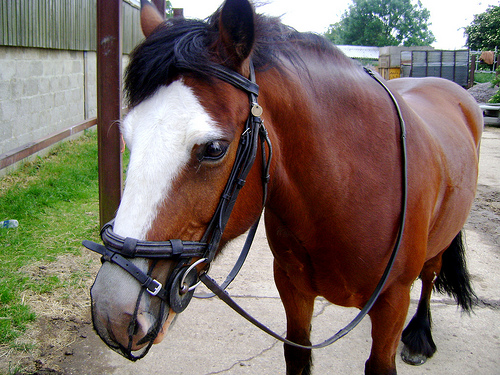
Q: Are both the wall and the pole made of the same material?
A: No, the wall is made of concrete and the pole is made of metal.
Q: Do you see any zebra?
A: No, there are no zebras.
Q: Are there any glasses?
A: No, there are no glasses.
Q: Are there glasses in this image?
A: No, there are no glasses.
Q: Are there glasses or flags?
A: No, there are no glasses or flags.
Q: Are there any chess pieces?
A: No, there are no chess pieces.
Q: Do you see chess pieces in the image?
A: No, there are no chess pieces.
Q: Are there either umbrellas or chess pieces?
A: No, there are no chess pieces or umbrellas.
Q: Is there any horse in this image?
A: Yes, there is a horse.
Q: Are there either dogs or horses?
A: Yes, there is a horse.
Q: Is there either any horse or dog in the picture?
A: Yes, there is a horse.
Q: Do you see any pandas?
A: No, there are no pandas.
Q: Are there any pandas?
A: No, there are no pandas.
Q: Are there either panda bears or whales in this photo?
A: No, there are no panda bears or whales.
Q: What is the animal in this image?
A: The animal is a horse.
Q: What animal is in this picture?
A: The animal is a horse.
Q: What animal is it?
A: The animal is a horse.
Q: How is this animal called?
A: This is a horse.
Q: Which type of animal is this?
A: This is a horse.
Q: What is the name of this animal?
A: This is a horse.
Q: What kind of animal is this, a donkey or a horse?
A: This is a horse.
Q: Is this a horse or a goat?
A: This is a horse.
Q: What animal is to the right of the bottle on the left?
A: The animal is a horse.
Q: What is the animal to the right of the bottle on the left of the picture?
A: The animal is a horse.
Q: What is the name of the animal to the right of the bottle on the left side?
A: The animal is a horse.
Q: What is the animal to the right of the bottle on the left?
A: The animal is a horse.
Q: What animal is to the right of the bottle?
A: The animal is a horse.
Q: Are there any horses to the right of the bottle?
A: Yes, there is a horse to the right of the bottle.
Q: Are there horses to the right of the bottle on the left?
A: Yes, there is a horse to the right of the bottle.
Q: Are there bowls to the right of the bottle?
A: No, there is a horse to the right of the bottle.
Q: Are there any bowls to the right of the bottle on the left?
A: No, there is a horse to the right of the bottle.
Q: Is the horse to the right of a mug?
A: No, the horse is to the right of a bottle.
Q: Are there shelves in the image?
A: No, there are no shelves.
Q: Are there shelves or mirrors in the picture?
A: No, there are no shelves or mirrors.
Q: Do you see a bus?
A: No, there are no buses.